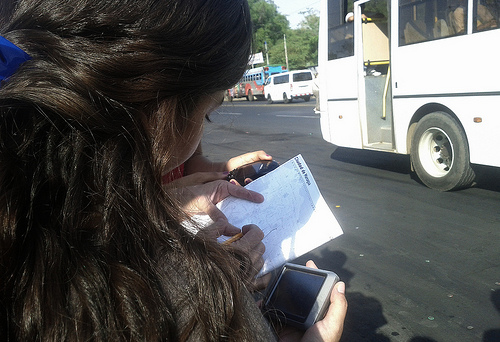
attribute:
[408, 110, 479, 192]
tire — black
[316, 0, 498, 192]
wheel — white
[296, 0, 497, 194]
bus — white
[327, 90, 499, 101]
stripe — black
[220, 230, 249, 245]
pencil — yellow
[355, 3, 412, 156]
door — open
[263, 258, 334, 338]
gps — silver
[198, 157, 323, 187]
phone — black, cellular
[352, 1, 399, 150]
door — open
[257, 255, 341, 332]
device — electronic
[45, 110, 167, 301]
hair — long, brunette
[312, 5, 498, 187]
bus — white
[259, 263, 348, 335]
electronic device — small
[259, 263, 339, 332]
gps — silver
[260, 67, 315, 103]
van — white